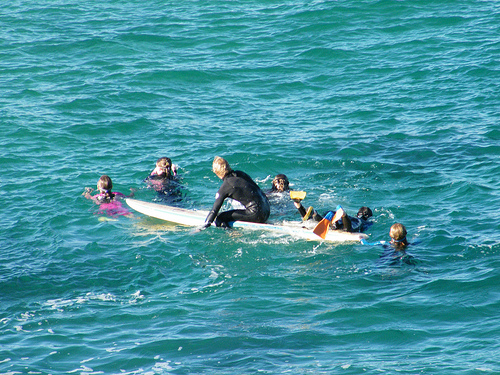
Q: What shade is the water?
A: Blue.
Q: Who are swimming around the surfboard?
A: Children.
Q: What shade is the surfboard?
A: Yellow.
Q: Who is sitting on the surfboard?
A: A man.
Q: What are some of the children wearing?
A: Flippers.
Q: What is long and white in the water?
A: The surfboard.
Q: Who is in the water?
A: Children.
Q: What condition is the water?
A: Calm.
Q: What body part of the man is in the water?
A: An arm.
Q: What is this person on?
A: Surfboard.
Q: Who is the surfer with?
A: Swimmers.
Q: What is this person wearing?
A: Wetsuit.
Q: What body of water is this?
A: Ocean.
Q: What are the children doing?
A: Swimming.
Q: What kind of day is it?
A: Sunny.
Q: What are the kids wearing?
A: Wetsuits.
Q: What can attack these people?
A: Shark.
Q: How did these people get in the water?
A: From the beach.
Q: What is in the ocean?
A: A surfboard.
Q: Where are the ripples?
A: In the ocean.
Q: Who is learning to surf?
A: The people.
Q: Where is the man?
A: On a surfboard.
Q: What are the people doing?
A: Swimming.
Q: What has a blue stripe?
A: A surfboard.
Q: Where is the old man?
A: On a surfboard.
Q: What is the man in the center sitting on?
A: A surfboard.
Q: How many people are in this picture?
A: 6.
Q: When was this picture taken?
A: Daytime.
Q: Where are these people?
A: In the ocean.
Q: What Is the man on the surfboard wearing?
A: A wetsuit.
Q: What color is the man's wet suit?
A: Black.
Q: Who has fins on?
A: The boy 2nd from the right.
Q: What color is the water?
A: Blue.